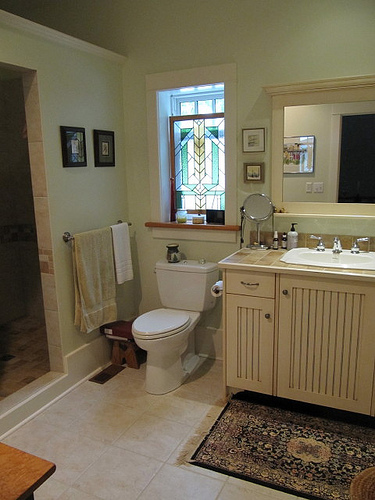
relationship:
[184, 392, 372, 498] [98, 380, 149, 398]
rug on floor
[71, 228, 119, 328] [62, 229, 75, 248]
towel on towel rack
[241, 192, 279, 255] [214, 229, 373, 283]
mirror on counter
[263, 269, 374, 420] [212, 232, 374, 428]
door on cabinet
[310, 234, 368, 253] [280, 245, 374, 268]
faucet of sink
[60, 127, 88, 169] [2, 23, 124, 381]
frame on wall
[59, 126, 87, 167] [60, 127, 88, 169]
picture in frame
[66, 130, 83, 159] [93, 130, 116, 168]
picture in frame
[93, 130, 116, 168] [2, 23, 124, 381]
frame on wall